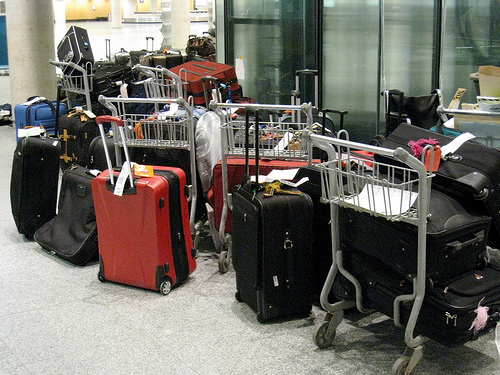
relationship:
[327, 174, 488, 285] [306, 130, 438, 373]
bag on cart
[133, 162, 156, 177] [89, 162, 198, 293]
tag on case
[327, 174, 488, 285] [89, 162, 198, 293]
bag near case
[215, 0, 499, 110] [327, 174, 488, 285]
wall behind bag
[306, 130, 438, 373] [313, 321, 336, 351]
cart has wheel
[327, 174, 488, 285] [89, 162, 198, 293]
bag and case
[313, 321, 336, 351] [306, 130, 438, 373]
wheel on cart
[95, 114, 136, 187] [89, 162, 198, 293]
handle on case